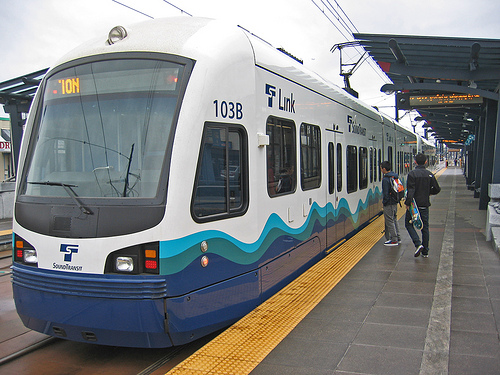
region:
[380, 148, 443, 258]
two people standing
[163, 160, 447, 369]
a thick yellow line beside the truck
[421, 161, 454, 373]
a faded white line on the pavement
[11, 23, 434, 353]
a white and blue train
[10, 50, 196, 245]
a window with the 10N illuminated in the top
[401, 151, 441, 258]
a dark haired male carrying a skateboard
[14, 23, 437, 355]
the train has wavy blue lines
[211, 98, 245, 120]
the number 103B in blue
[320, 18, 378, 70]
utility lines overhead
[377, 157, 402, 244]
male carrying an orange and white backpack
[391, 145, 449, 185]
the head of a man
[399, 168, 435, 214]
the arm of a man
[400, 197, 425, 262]
the leg of a man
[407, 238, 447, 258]
the feet of a man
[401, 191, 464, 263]
a man wearing pants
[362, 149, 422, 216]
a man wearing a jacket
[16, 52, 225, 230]
the window on a train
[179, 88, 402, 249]
the windows on the side of a train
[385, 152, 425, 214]
a man wearing a backpack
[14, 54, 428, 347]
a train at a train station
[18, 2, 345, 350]
white and blue train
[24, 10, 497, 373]
white and blue train at station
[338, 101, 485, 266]
people waiting to board train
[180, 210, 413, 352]
yellow keep back area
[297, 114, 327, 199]
window in front of train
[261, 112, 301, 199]
window on side of train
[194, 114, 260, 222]
window on side of train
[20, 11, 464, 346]
train at the station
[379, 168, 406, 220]
person wearing a backpack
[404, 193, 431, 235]
person holding a skateboard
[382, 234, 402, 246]
Boy wearing shoes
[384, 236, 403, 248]
Boy is wearing shoes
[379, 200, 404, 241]
Boy wearing pants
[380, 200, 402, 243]
Boy is wearing pants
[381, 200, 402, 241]
Boy wearing gray pants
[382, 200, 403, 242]
Boy is wearing gray pants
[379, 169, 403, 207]
Boy wearing a sweatshirt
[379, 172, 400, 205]
Boy is wearing a sweatshirt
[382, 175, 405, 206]
Boy wearing a backpack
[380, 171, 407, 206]
Boy is wearing a backpack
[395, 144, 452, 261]
person wearing black jacket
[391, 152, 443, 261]
person wearing blue jeans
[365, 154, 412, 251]
person wearing back pack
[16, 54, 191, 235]
front windshield of train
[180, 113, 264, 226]
side mirror of train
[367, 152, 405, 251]
person wearing jeans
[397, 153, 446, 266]
person holding skateboard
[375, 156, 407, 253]
person wearing a jacket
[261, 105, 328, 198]
windows on a train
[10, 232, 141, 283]
head light of a blue train